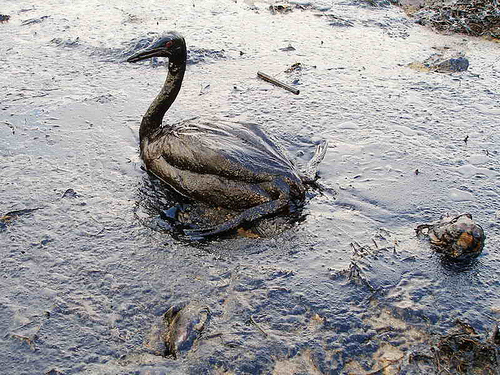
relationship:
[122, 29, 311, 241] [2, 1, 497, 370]
duck in oil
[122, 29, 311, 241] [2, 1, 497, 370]
duck stuck in oil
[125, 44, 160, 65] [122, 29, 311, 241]
beak of duck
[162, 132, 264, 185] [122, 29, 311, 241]
wing of duck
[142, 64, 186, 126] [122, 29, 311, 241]
neck of duck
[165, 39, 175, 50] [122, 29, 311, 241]
eye of duck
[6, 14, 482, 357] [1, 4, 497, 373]
debris in muck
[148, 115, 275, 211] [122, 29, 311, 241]
body of duck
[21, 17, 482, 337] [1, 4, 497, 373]
ripples in muck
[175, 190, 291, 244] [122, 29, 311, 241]
leg of a duck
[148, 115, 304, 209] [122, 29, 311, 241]
body of a duck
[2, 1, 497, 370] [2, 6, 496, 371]
oil contaminating water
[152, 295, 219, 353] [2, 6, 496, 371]
rock in water